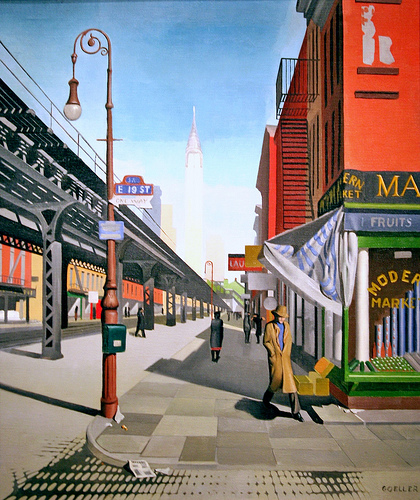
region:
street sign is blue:
[114, 170, 152, 194]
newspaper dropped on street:
[129, 458, 154, 476]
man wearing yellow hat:
[255, 307, 306, 424]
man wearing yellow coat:
[264, 307, 305, 420]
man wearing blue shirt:
[254, 305, 305, 422]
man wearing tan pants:
[255, 303, 306, 421]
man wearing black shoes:
[261, 302, 306, 420]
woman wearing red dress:
[208, 310, 223, 361]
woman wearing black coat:
[209, 314, 224, 359]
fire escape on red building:
[283, 55, 317, 229]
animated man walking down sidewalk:
[263, 305, 307, 423]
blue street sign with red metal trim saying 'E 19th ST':
[112, 173, 159, 197]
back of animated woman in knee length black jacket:
[207, 307, 224, 364]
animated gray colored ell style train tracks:
[1, 64, 233, 359]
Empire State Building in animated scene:
[181, 103, 207, 284]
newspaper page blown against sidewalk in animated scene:
[123, 453, 156, 483]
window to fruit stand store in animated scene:
[348, 211, 418, 385]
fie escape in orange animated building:
[273, 54, 321, 237]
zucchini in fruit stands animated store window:
[345, 360, 375, 375]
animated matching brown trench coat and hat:
[260, 303, 299, 396]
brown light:
[61, 81, 94, 125]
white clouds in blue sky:
[12, 8, 50, 44]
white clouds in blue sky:
[116, 19, 162, 64]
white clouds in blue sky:
[121, 57, 155, 97]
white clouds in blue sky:
[130, 93, 156, 129]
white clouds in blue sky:
[189, 21, 225, 66]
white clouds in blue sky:
[222, 56, 255, 87]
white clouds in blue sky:
[217, 83, 243, 117]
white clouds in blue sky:
[214, 143, 239, 181]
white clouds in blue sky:
[210, 193, 234, 222]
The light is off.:
[57, 78, 82, 125]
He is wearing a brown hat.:
[265, 304, 294, 316]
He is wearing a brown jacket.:
[260, 315, 301, 395]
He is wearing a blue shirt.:
[270, 317, 293, 346]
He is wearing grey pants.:
[251, 391, 311, 418]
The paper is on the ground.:
[127, 454, 158, 481]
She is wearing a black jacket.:
[205, 307, 227, 358]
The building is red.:
[246, 92, 412, 227]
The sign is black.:
[306, 166, 418, 213]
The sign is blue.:
[104, 168, 153, 210]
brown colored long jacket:
[254, 295, 300, 413]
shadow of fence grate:
[69, 445, 187, 492]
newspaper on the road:
[126, 448, 151, 477]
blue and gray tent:
[275, 217, 346, 320]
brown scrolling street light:
[63, 45, 138, 446]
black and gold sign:
[320, 169, 402, 217]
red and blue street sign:
[113, 165, 172, 212]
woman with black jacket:
[201, 304, 240, 378]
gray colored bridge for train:
[5, 95, 207, 330]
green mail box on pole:
[102, 313, 133, 363]